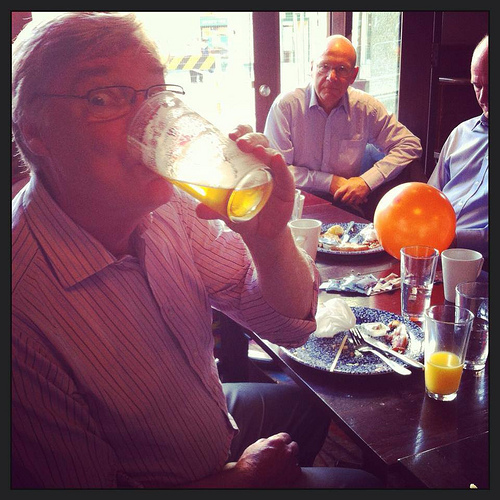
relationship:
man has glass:
[7, 16, 319, 499] [124, 94, 275, 227]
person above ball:
[265, 19, 422, 201] [365, 180, 467, 267]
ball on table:
[365, 180, 467, 267] [175, 172, 493, 484]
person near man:
[265, 19, 422, 201] [7, 16, 319, 499]